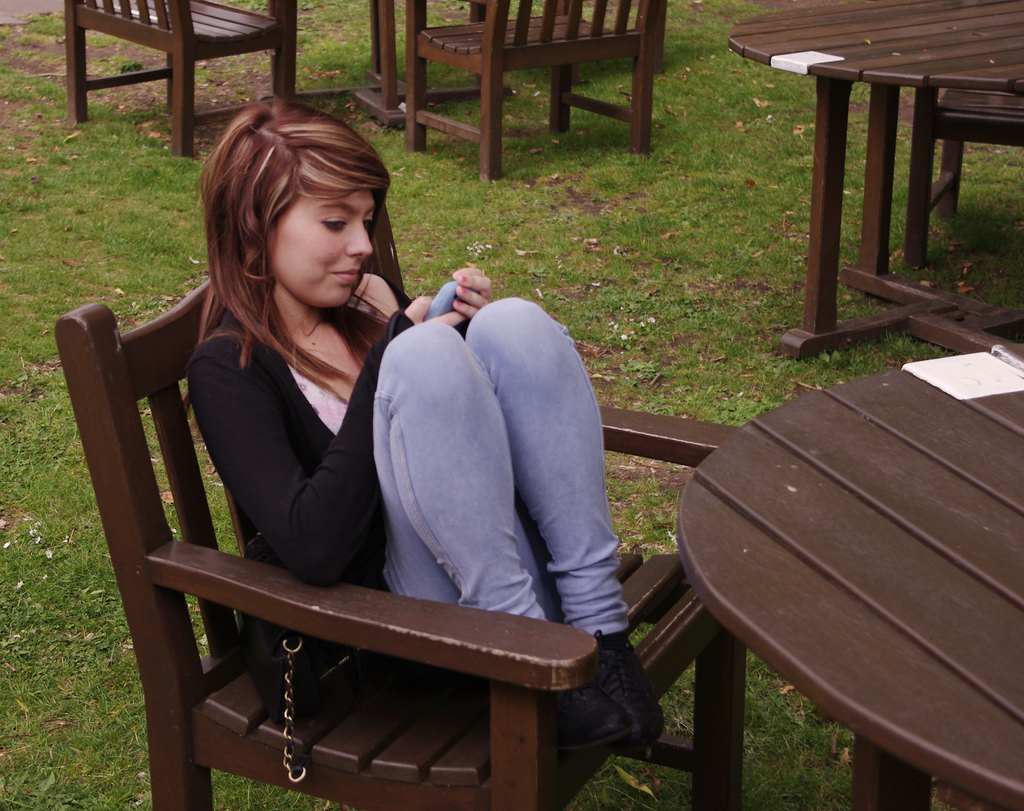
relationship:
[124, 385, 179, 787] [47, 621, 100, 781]
chair on the grass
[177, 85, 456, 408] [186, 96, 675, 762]
hair on girl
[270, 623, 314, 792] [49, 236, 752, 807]
chain on chair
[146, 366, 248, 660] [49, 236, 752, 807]
panel on chair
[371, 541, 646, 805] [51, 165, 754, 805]
panel on chair